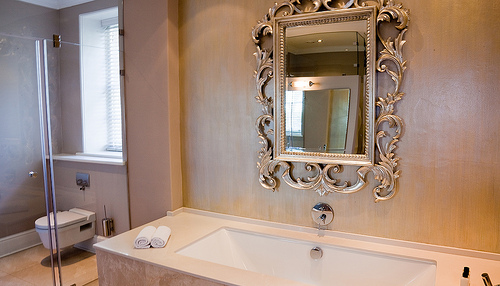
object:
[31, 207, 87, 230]
lid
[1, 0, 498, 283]
bathroom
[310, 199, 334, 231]
faucet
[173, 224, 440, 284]
sink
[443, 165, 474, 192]
ground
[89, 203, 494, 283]
vanity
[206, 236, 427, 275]
tub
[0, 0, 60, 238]
wall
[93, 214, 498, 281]
shelf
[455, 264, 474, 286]
small bottles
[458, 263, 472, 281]
black lids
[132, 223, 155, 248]
towel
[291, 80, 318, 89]
lights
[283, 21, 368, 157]
reflection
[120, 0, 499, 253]
brown wall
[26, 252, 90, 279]
floor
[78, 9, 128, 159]
window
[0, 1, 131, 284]
room divider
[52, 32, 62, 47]
bracket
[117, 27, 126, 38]
bracket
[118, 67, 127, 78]
bracket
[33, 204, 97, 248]
thumb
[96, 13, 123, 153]
blinds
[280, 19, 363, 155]
glass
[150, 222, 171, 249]
towels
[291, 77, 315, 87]
light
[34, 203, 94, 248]
toilet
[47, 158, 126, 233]
wall